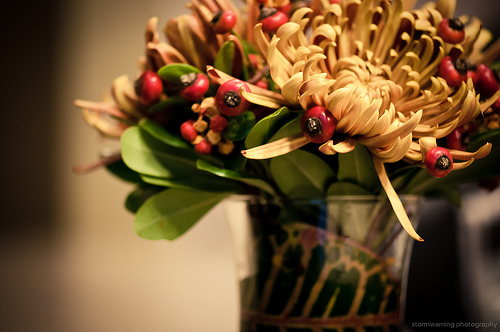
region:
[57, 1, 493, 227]
this is a bouquet of flowers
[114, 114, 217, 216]
green leafs on flowers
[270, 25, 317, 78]
tan petals on flowers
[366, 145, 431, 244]
flower petal hanging down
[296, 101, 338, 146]
red bulb on flower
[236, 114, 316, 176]
flower petal stick out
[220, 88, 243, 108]
black end on buln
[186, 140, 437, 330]
vase for the flowers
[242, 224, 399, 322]
green detail on vase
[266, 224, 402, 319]
tan trim on vase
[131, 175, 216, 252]
green leaves on the flowers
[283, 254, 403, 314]
design on the jug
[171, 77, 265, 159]
red flowers in jug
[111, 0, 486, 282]
a clear view of flowers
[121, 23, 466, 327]
a superb view of flowers in jug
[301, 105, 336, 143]
a red berry on a flower arrangement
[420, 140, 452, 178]
a red berry on a flower arrangement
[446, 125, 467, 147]
a red berry on a flower arrangement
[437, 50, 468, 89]
a red berry on a flower arrangement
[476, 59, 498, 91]
a red berry on a flower arrangement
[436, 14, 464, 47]
a red berry on a flower arrangement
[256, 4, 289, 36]
a red berry on a flower arrangement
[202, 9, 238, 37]
a red berry on a flower arrangement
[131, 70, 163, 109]
a red berry on a flower arrangement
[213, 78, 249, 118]
red part of plant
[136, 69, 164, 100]
red part of plant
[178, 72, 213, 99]
red part of plant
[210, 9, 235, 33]
red part of plant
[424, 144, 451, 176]
red part of plant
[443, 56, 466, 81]
red part of plant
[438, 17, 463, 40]
red part of plant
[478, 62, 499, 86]
red part of plant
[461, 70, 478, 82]
red part of plant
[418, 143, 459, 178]
a red berry in an arrangement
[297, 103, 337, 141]
a red berry in an arrangement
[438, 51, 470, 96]
a red berry in an arrangement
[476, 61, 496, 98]
a red berry in an arrangement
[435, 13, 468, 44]
a red berry in an arrangement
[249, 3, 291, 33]
a red berry in an arrangement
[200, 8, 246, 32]
a red berry in an arrangement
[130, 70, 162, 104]
a red berry in an arrangement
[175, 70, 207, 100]
a red berry in an arrangement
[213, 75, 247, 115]
a red berry in an arrangement